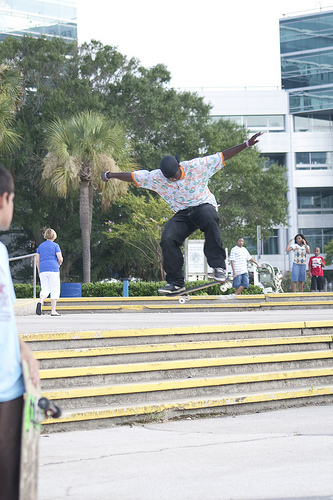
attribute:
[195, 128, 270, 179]
arm — extended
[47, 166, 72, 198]
palm — yellow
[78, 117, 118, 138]
palm — green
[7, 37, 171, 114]
tree — big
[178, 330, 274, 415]
steps — yellow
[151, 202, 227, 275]
pants — black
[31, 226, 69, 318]
woman — walking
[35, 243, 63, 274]
shirt — blue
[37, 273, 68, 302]
pants — white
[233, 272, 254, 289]
shorts — blue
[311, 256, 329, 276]
shirt — red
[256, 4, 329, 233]
building — tall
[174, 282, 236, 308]
wheels — white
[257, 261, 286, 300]
stroller — gray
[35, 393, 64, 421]
wheel — black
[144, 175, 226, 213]
shirt — multi-colored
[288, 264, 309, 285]
shorts — blue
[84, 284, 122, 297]
bushes — green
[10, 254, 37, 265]
handrail — white